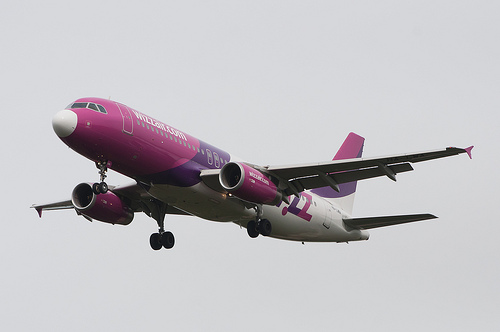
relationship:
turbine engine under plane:
[218, 160, 284, 207] [29, 95, 474, 251]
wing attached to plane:
[199, 145, 477, 197] [29, 95, 474, 251]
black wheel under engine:
[257, 217, 273, 237] [218, 160, 284, 207]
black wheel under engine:
[244, 218, 260, 239] [218, 160, 284, 207]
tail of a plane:
[331, 131, 367, 161] [29, 95, 474, 251]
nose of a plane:
[52, 110, 80, 138] [29, 95, 474, 251]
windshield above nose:
[64, 100, 108, 114] [52, 110, 80, 138]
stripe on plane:
[151, 142, 230, 187] [29, 95, 474, 251]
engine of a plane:
[71, 182, 135, 227] [29, 95, 474, 251]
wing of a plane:
[28, 184, 143, 217] [29, 95, 474, 251]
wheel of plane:
[98, 180, 109, 194] [29, 95, 474, 251]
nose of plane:
[52, 110, 80, 138] [29, 95, 474, 251]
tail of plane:
[331, 131, 367, 161] [29, 95, 474, 251]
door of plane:
[116, 101, 135, 136] [29, 95, 474, 251]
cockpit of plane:
[69, 99, 109, 120] [29, 95, 474, 251]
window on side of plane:
[135, 120, 142, 128] [29, 95, 474, 251]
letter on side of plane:
[135, 111, 143, 123] [29, 95, 474, 251]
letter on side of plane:
[144, 116, 152, 127] [29, 95, 474, 251]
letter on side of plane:
[165, 123, 172, 134] [29, 95, 474, 251]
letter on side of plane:
[171, 126, 177, 138] [29, 95, 474, 251]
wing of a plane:
[199, 145, 477, 197] [29, 95, 474, 251]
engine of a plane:
[218, 160, 284, 207] [29, 95, 474, 251]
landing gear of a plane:
[94, 163, 272, 251] [29, 95, 474, 251]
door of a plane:
[116, 101, 135, 136] [29, 95, 474, 251]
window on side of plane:
[200, 147, 208, 157] [29, 95, 474, 251]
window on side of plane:
[168, 133, 176, 144] [29, 95, 474, 251]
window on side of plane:
[153, 124, 161, 137] [29, 95, 474, 251]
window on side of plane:
[145, 123, 151, 133] [29, 95, 474, 251]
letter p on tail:
[288, 190, 314, 223] [278, 190, 370, 242]